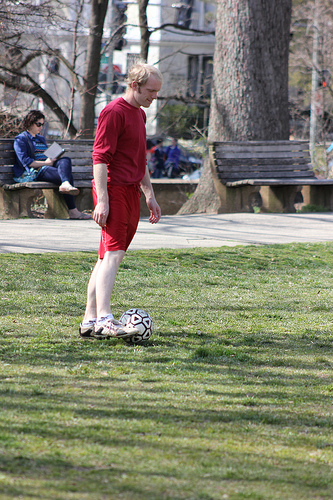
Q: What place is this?
A: It is a park.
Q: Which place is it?
A: It is a park.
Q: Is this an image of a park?
A: Yes, it is showing a park.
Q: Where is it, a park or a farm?
A: It is a park.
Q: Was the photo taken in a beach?
A: No, the picture was taken in a park.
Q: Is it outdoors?
A: Yes, it is outdoors.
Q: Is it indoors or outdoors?
A: It is outdoors.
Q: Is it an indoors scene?
A: No, it is outdoors.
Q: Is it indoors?
A: No, it is outdoors.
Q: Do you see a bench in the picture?
A: Yes, there is a bench.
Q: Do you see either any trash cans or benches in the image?
A: Yes, there is a bench.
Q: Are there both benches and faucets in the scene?
A: No, there is a bench but no faucets.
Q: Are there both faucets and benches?
A: No, there is a bench but no faucets.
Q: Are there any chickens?
A: No, there are no chickens.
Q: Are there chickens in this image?
A: No, there are no chickens.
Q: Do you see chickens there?
A: No, there are no chickens.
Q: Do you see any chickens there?
A: No, there are no chickens.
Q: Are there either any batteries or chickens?
A: No, there are no chickens or batteries.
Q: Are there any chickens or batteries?
A: No, there are no chickens or batteries.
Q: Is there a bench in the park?
A: Yes, there is a bench in the park.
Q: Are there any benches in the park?
A: Yes, there is a bench in the park.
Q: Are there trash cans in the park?
A: No, there is a bench in the park.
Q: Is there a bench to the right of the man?
A: Yes, there is a bench to the right of the man.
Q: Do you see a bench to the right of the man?
A: Yes, there is a bench to the right of the man.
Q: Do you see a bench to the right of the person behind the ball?
A: Yes, there is a bench to the right of the man.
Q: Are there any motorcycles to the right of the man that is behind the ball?
A: No, there is a bench to the right of the man.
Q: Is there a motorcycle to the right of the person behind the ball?
A: No, there is a bench to the right of the man.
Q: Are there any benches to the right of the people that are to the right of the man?
A: Yes, there is a bench to the right of the people.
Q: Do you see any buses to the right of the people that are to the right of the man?
A: No, there is a bench to the right of the people.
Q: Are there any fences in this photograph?
A: No, there are no fences.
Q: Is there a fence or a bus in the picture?
A: No, there are no fences or buses.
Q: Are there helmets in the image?
A: No, there are no helmets.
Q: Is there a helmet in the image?
A: No, there are no helmets.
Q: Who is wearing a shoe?
A: The man is wearing a shoe.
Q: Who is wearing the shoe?
A: The man is wearing a shoe.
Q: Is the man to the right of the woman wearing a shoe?
A: Yes, the man is wearing a shoe.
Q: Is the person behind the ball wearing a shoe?
A: Yes, the man is wearing a shoe.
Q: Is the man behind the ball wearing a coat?
A: No, the man is wearing a shoe.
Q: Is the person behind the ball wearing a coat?
A: No, the man is wearing a shoe.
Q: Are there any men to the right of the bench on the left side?
A: Yes, there is a man to the right of the bench.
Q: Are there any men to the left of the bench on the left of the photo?
A: No, the man is to the right of the bench.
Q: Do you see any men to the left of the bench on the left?
A: No, the man is to the right of the bench.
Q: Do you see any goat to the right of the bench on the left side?
A: No, there is a man to the right of the bench.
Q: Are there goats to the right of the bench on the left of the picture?
A: No, there is a man to the right of the bench.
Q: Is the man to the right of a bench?
A: Yes, the man is to the right of a bench.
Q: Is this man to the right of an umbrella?
A: No, the man is to the right of a bench.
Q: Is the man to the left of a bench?
A: No, the man is to the right of a bench.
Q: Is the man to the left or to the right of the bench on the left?
A: The man is to the right of the bench.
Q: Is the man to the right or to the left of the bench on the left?
A: The man is to the right of the bench.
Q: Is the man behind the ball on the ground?
A: Yes, the man is behind the ball.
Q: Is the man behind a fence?
A: No, the man is behind the ball.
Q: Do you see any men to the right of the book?
A: Yes, there is a man to the right of the book.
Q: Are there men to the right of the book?
A: Yes, there is a man to the right of the book.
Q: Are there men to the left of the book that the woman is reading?
A: No, the man is to the right of the book.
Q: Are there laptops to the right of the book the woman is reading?
A: No, there is a man to the right of the book.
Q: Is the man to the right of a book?
A: Yes, the man is to the right of a book.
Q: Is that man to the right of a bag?
A: No, the man is to the right of a book.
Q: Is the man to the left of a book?
A: No, the man is to the right of a book.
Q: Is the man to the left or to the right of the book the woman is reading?
A: The man is to the right of the book.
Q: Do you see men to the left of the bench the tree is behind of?
A: Yes, there is a man to the left of the bench.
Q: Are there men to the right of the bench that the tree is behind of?
A: No, the man is to the left of the bench.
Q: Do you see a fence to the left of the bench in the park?
A: No, there is a man to the left of the bench.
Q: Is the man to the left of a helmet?
A: No, the man is to the left of a bench.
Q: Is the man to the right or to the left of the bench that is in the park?
A: The man is to the left of the bench.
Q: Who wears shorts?
A: The man wears shorts.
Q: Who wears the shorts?
A: The man wears shorts.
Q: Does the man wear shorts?
A: Yes, the man wears shorts.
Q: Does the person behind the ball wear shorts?
A: Yes, the man wears shorts.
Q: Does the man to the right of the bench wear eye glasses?
A: No, the man wears shorts.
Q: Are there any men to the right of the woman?
A: Yes, there is a man to the right of the woman.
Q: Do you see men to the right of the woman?
A: Yes, there is a man to the right of the woman.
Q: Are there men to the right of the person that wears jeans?
A: Yes, there is a man to the right of the woman.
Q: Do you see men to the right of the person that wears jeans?
A: Yes, there is a man to the right of the woman.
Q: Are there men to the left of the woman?
A: No, the man is to the right of the woman.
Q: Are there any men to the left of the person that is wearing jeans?
A: No, the man is to the right of the woman.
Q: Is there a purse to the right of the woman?
A: No, there is a man to the right of the woman.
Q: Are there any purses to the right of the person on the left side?
A: No, there is a man to the right of the woman.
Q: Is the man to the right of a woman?
A: Yes, the man is to the right of a woman.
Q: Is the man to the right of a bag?
A: No, the man is to the right of a woman.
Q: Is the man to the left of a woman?
A: No, the man is to the right of a woman.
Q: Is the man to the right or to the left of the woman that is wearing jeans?
A: The man is to the right of the woman.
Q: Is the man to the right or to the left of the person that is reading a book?
A: The man is to the right of the woman.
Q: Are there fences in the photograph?
A: No, there are no fences.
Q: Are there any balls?
A: Yes, there is a ball.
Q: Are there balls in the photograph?
A: Yes, there is a ball.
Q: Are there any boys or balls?
A: Yes, there is a ball.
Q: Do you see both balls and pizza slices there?
A: No, there is a ball but no pizza slices.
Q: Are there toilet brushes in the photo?
A: No, there are no toilet brushes.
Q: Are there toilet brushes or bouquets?
A: No, there are no toilet brushes or bouquets.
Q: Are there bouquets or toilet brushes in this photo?
A: No, there are no toilet brushes or bouquets.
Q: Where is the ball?
A: The ball is on the ground.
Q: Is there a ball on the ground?
A: Yes, there is a ball on the ground.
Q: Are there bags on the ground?
A: No, there is a ball on the ground.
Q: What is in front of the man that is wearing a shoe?
A: The ball is in front of the man.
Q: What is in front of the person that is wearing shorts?
A: The ball is in front of the man.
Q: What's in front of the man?
A: The ball is in front of the man.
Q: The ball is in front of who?
A: The ball is in front of the man.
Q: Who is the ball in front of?
A: The ball is in front of the man.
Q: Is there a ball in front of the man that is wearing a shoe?
A: Yes, there is a ball in front of the man.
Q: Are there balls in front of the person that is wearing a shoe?
A: Yes, there is a ball in front of the man.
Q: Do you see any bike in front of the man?
A: No, there is a ball in front of the man.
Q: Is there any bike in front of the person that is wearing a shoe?
A: No, there is a ball in front of the man.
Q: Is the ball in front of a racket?
A: No, the ball is in front of a man.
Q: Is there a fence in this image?
A: No, there are no fences.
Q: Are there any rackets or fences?
A: No, there are no fences or rackets.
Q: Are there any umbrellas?
A: No, there are no umbrellas.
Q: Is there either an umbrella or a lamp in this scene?
A: No, there are no umbrellas or lamps.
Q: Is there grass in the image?
A: Yes, there is grass.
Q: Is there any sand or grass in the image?
A: Yes, there is grass.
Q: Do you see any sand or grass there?
A: Yes, there is grass.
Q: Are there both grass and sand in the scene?
A: No, there is grass but no sand.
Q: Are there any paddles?
A: No, there are no paddles.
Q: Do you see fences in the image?
A: No, there are no fences.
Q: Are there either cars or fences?
A: No, there are no fences or cars.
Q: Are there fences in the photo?
A: No, there are no fences.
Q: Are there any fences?
A: No, there are no fences.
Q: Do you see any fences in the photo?
A: No, there are no fences.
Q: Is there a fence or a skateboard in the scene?
A: No, there are no fences or skateboards.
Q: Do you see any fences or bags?
A: No, there are no fences or bags.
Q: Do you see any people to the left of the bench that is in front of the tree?
A: Yes, there are people to the left of the bench.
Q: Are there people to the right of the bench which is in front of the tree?
A: No, the people are to the left of the bench.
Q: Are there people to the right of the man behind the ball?
A: Yes, there are people to the right of the man.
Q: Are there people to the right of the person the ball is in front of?
A: Yes, there are people to the right of the man.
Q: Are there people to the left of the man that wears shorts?
A: No, the people are to the right of the man.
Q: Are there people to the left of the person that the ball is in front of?
A: No, the people are to the right of the man.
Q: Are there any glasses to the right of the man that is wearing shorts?
A: No, there are people to the right of the man.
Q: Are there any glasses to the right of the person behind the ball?
A: No, there are people to the right of the man.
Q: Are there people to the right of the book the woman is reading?
A: Yes, there are people to the right of the book.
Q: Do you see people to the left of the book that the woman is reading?
A: No, the people are to the right of the book.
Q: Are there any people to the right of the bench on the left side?
A: Yes, there are people to the right of the bench.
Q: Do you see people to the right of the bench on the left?
A: Yes, there are people to the right of the bench.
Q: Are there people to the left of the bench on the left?
A: No, the people are to the right of the bench.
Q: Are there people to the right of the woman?
A: Yes, there are people to the right of the woman.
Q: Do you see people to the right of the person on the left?
A: Yes, there are people to the right of the woman.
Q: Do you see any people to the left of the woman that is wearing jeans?
A: No, the people are to the right of the woman.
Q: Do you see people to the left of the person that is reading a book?
A: No, the people are to the right of the woman.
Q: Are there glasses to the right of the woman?
A: No, there are people to the right of the woman.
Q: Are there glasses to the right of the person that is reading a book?
A: No, there are people to the right of the woman.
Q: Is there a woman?
A: Yes, there is a woman.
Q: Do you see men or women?
A: Yes, there is a woman.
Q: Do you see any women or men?
A: Yes, there is a woman.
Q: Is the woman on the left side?
A: Yes, the woman is on the left of the image.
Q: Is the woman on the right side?
A: No, the woman is on the left of the image.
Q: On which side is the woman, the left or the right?
A: The woman is on the left of the image.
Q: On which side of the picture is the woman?
A: The woman is on the left of the image.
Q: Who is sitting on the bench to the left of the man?
A: The woman is sitting on the bench.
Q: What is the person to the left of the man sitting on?
A: The woman is sitting on the bench.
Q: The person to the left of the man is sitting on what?
A: The woman is sitting on the bench.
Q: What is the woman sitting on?
A: The woman is sitting on the bench.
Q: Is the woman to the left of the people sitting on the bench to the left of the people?
A: Yes, the woman is sitting on the bench.